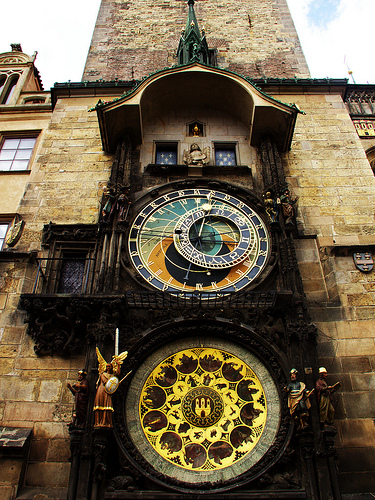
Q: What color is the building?
A: Brown.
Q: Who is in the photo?
A: Nobody.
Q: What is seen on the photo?
A: Tower clock.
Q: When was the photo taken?
A: During the day.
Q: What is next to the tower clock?
A: Statues.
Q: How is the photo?
A: Clear.